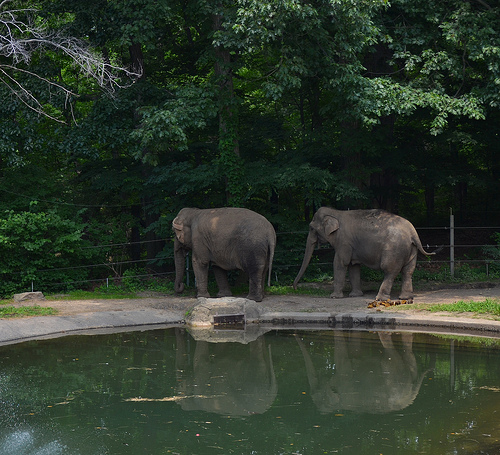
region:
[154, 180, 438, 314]
two elephants in a zoo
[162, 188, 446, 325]
two elephants by a pond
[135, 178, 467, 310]
two elephants by a fence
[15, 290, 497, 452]
a pond in a zoo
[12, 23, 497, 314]
trees beyond the elephants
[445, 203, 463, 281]
a pole on a fence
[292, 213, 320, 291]
A trunk on an elephant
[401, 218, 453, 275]
the tail of an elephant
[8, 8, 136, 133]
a tree branch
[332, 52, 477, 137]
leaves on a tree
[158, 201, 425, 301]
The elephants are grey.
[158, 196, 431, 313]
The elephants are standing.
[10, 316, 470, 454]
The water is calm.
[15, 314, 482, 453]
The water is murky.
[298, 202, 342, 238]
His ears are small.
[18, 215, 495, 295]
The fence is short.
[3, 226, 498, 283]
The fence is metal.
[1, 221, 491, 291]
The fence is grey.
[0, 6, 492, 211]
The trees are leafy.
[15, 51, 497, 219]
The trees are green.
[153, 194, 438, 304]
two gray elephants standing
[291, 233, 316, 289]
one gray elephant trunk pointing down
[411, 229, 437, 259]
one gray elephant tail pointing up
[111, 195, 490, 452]
two gray elephants near pond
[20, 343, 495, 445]
elephant reflections on green pond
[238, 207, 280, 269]
one gray elephant backside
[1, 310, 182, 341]
light gray stone edge of pond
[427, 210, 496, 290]
metal fencing with metal pole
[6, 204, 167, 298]
green leafy bush behind metal fence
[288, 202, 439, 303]
partially shadowed gray elephant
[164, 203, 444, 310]
two elephants walking by a fence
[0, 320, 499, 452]
a small pool of water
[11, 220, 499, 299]
a wire fence next to the elephants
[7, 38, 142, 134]
a few dead looking branches in the corner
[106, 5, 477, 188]
many green leafy trees by the elephants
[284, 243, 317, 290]
the trunk of the elephant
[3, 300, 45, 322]
some grass on the ground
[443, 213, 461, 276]
a pole holding the fence together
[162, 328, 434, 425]
the reflection of the elephants in the water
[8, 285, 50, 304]
a rock on the ground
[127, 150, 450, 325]
two elephants on the ground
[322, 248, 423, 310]
legs of the elephant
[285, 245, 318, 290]
trunk of the elephant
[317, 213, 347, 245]
ear of the elephant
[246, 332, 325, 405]
water next to elephants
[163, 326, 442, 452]
reflection of the elephants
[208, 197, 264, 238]
back of the elephant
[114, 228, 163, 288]
fence next to the elephants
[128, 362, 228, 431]
stuff in the water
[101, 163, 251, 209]
leaves on a tree